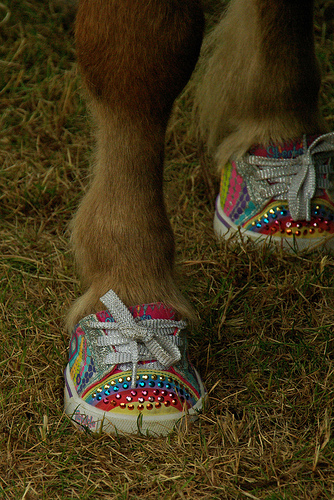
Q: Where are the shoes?
A: On the horses hooves.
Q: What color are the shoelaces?
A: Grey.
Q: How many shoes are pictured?
A: Two.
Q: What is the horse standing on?
A: Grass.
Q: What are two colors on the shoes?
A: Pink and blue.